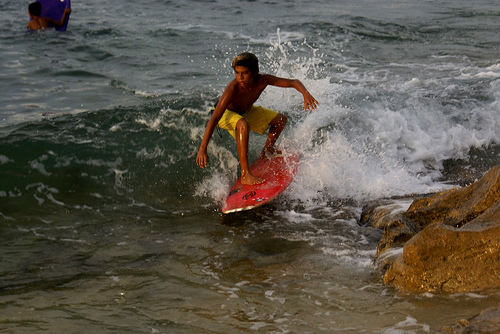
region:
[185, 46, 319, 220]
a boy is on a surfboard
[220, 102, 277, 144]
the boy is wearing shorts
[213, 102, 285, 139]
the shorts are yellow in color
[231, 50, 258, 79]
the boy has blonde hair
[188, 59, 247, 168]
the boy has his arm extended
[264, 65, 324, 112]
the boy has his arm bent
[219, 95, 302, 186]
the boy has his legs bent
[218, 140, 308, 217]
the surfboard is red in color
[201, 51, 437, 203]
the surfer is splashing water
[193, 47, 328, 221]
the surfer is riding a wave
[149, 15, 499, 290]
a boy surfing next to a boulder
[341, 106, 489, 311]
a boulder in the ocean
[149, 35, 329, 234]
a boy on a red surfboard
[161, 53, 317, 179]
a boy wearing a yellow bathing suit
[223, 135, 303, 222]
the feet of the boy on the surfboard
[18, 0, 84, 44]
a person with a blue surfboard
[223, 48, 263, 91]
the head of a boy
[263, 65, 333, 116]
the arm of a boy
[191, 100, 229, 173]
the arm of a boy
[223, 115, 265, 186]
the leg of a boy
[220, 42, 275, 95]
head of a person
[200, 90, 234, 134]
arn of a person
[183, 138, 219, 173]
hand of a person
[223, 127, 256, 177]
leg of a person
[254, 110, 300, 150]
leg of a person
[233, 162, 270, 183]
feet of a person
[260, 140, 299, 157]
feet of a person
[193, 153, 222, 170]
hand of a person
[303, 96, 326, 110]
hand of a person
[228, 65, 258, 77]
eye of a person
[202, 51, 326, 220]
the surfer is splashing water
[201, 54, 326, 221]
the surfer is in front of the wave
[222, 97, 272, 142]
the surfer is wearing yellow pants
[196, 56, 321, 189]
the surfer is bending down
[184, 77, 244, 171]
the surfer has his arm extended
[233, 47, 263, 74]
the surfer has blonde hair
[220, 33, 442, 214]
the water is splashin about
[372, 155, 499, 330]
a bed of rocks is besides the surfer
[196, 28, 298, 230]
child on a surfboard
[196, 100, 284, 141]
boy wearing yellow shorts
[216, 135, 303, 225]
boy on a red surfboard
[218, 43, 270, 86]
boy with blonde hair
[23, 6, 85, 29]
person swimming into the beach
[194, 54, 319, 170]
boy with his arms out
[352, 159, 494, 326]
water on the rocks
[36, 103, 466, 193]
waves crashing on the beach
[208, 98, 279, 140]
boy wearing yellow shorts